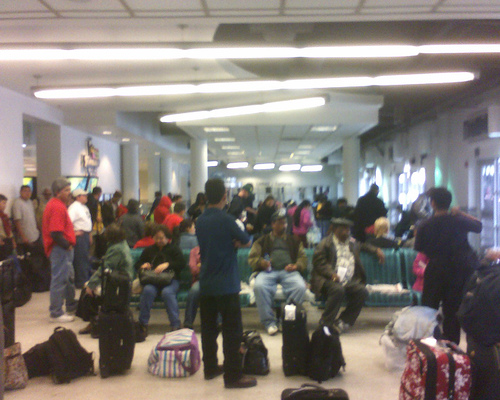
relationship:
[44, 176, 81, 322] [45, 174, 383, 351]
man in group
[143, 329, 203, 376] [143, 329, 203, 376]
backpack for backpack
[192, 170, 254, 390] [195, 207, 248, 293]
man has blue shirt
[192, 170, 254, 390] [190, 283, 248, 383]
man has pants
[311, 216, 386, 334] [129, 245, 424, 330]
man on bench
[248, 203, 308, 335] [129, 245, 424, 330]
man on bench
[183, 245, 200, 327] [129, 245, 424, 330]
people on bench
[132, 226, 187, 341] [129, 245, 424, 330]
people on bench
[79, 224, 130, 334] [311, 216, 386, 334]
people on man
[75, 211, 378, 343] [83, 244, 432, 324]
people on bench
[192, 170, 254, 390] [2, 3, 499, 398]
man on airport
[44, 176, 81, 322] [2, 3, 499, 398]
man on airport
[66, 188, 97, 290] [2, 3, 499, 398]
person on airport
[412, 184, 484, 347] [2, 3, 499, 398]
person on airport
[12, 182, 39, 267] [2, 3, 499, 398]
person on airport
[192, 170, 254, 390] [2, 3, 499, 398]
man standing in airport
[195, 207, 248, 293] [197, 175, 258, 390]
blue shirt on man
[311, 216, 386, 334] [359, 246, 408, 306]
man sitting on green bench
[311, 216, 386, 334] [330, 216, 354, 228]
man in brown hat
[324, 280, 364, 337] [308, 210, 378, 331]
trousers on man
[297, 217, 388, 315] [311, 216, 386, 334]
jacket on man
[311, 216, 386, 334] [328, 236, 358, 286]
man with shirt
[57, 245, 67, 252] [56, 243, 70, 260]
hand in pocket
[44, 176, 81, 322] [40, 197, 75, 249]
man with shirt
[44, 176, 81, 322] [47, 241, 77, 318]
man with jeans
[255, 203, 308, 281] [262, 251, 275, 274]
man holding water bottle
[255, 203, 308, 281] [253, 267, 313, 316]
man sitting in jeans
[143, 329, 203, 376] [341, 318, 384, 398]
backpack on ground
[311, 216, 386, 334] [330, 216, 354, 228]
man wearing brown hat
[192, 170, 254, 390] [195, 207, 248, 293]
man wearing blue shirt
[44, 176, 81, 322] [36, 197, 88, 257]
man wearing red shirt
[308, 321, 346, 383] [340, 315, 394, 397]
luggage on ground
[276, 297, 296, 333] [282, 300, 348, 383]
tag on suitcase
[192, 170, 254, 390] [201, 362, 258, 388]
man wearing shoes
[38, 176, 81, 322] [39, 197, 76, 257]
man wearing red shirt